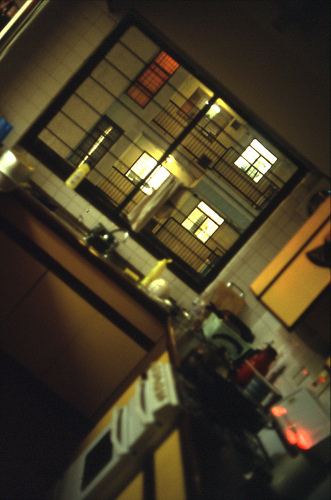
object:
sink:
[30, 193, 94, 259]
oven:
[66, 373, 188, 500]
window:
[37, 25, 302, 287]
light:
[122, 51, 179, 108]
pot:
[172, 308, 291, 411]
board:
[0, 0, 331, 500]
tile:
[8, 0, 330, 496]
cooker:
[64, 317, 264, 500]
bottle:
[142, 258, 173, 287]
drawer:
[150, 430, 186, 499]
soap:
[122, 266, 140, 282]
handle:
[110, 373, 156, 451]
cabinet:
[250, 196, 331, 331]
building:
[0, 0, 330, 500]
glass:
[80, 429, 113, 496]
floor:
[0, 420, 55, 500]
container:
[235, 346, 278, 386]